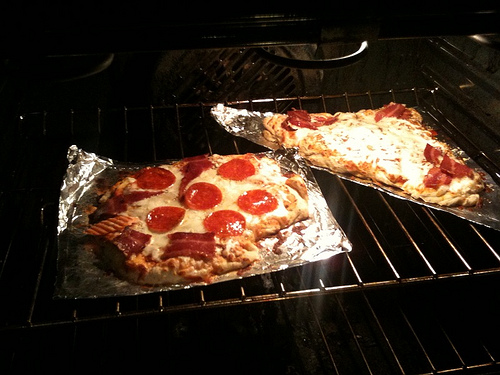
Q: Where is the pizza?
A: In the oven.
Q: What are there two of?
A: Pizzas.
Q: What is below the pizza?
A: Tin foil.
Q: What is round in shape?
A: The pizza.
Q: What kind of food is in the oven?
A: Pizza.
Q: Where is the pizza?
A: In the oven.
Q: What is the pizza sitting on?
A: Foil.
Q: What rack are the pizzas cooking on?
A: Top.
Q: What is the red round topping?
A: Pepperoni.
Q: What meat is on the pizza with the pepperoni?
A: Bacon.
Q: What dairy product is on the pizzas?
A: Cheese.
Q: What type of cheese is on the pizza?
A: Mozzarella.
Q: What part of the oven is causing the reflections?
A: Light.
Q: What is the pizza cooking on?
A: Aluminum.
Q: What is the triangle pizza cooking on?
A: Aluminum.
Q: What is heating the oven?
A: The coil heating.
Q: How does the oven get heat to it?
A: Fan.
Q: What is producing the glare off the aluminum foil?
A: Light from oven.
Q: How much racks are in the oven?
A: 2.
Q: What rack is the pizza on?
A: Top.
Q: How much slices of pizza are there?
A: 2.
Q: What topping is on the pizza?
A: Pepperoni.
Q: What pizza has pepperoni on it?
A: Left pizza.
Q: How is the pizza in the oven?
A: Baked.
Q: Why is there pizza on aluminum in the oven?
A: To cook.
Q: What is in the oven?
A: Two pizzas.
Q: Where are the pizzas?
A: On a rack in the oven.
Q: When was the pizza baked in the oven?
A: Dinnertime.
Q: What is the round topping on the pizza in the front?
A: Pepperoni.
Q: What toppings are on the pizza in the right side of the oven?
A: Cheese and bacon.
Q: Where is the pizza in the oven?
A: Kitchen.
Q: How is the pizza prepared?
A: Homemade.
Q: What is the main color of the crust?
A: Brown.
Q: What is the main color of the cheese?
A: White.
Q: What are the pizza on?
A: Foil.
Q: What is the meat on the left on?
A: Pepperoni.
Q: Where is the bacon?
A: On both pizza.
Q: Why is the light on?
A: The door is open.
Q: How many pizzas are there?
A: 2.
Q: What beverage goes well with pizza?
A: Beer.